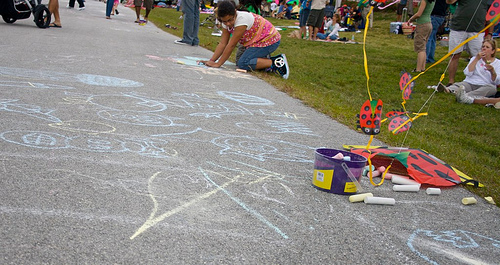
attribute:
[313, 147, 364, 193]
bucket — purple, plastic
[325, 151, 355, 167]
chalk — yellow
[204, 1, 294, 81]
girl — drawing, young, leaning, kneeling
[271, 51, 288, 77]
shoes — black, white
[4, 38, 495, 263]
drawings — chalk, present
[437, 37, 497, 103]
woman — sitting, blowing, wearing, older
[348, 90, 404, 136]
kite — red black, green, small, themed, ladybug, butterfly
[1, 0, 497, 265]
pavement — gray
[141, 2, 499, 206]
grass — green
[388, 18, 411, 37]
cooler — gray, white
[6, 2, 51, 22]
stroller — partial, tired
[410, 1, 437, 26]
tank top — green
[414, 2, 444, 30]
shirt — green